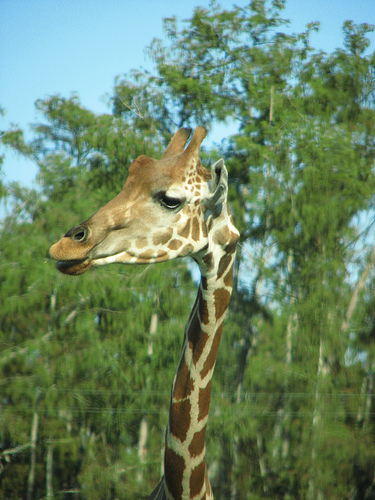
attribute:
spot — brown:
[187, 422, 207, 457]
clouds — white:
[3, 5, 185, 97]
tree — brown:
[206, 43, 373, 398]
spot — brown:
[166, 236, 183, 251]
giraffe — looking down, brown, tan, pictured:
[38, 114, 245, 498]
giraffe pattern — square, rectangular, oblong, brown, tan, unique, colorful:
[47, 125, 242, 498]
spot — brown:
[158, 442, 188, 498]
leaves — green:
[0, 2, 373, 499]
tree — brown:
[1, 2, 372, 495]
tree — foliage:
[270, 136, 373, 498]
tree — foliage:
[217, 38, 293, 498]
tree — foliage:
[269, 20, 318, 498]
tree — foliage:
[76, 264, 184, 499]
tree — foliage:
[1, 181, 132, 498]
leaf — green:
[337, 101, 354, 123]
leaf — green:
[306, 171, 319, 178]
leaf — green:
[297, 90, 305, 104]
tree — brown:
[226, 17, 372, 498]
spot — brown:
[194, 379, 223, 425]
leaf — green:
[23, 351, 35, 363]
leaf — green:
[119, 303, 131, 321]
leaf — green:
[119, 342, 131, 354]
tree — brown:
[1, 75, 217, 498]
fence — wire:
[7, 379, 372, 413]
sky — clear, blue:
[0, 0, 131, 94]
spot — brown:
[152, 248, 169, 265]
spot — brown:
[191, 429, 204, 457]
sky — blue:
[2, 2, 374, 187]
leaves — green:
[273, 351, 309, 389]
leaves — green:
[79, 325, 126, 365]